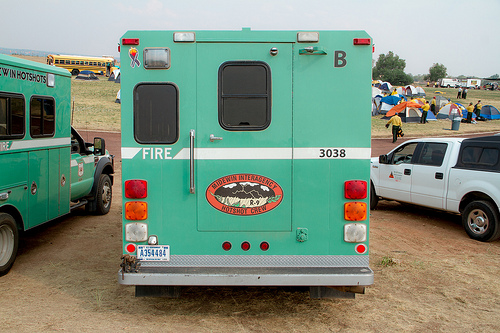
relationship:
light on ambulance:
[345, 180, 367, 199] [116, 27, 373, 296]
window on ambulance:
[135, 82, 177, 144] [116, 27, 373, 296]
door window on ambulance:
[218, 60, 272, 137] [116, 27, 373, 296]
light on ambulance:
[342, 222, 367, 243] [116, 27, 373, 296]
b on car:
[333, 50, 347, 69] [369, 133, 500, 241]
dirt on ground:
[2, 129, 496, 331] [1, 71, 498, 331]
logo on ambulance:
[201, 168, 284, 216] [116, 27, 373, 296]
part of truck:
[244, 27, 373, 295] [305, 170, 332, 208]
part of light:
[354, 223, 367, 242] [344, 224, 365, 245]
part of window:
[241, 60, 271, 132] [214, 60, 274, 131]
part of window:
[154, 80, 182, 146] [214, 60, 274, 131]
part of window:
[44, 93, 56, 138] [214, 60, 274, 131]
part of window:
[241, 60, 271, 132] [212, 66, 271, 135]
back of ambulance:
[119, 29, 370, 299] [116, 27, 373, 296]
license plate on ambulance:
[135, 242, 170, 264] [116, 27, 373, 296]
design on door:
[204, 173, 284, 215] [192, 34, 317, 254]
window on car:
[387, 133, 417, 165] [360, 130, 498, 247]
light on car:
[346, 176, 367, 200] [94, 18, 399, 301]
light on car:
[342, 199, 366, 220] [111, 28, 377, 298]